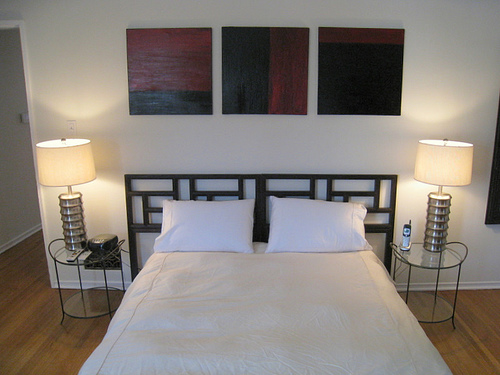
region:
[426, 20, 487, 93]
part of a white wall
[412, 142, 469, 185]
part of white lamp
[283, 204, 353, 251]
part of the left pillow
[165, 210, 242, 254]
part of the right pillow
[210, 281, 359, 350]
part of a white sheet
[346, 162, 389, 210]
part of the wooden part of the bed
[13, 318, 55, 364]
part of the floor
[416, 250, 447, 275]
part of a glassy furniture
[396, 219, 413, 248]
part of a cellphone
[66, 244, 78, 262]
part of a remote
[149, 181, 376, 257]
two white pillows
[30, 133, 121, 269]
lamp sitting on table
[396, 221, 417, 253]
phone sitting on stand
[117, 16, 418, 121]
three pictures hanging on the wall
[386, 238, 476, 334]
stand on wooden floor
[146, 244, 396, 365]
cream bed throw covering bed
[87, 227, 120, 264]
alarm clock on night stand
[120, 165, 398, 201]
wooden headboard with square pattern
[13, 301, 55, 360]
brown wooden floor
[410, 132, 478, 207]
cream lamp shade on lamp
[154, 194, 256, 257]
White pillow on a bed.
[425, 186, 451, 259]
Silver table lamp.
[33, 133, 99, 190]
White lamp shade.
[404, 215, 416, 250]
Portable phone beside bed.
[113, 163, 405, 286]
Wooden rectangular head board.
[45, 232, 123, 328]
Circular glass end table.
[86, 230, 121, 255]
Silver bedside clock radio.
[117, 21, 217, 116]
Red and black art work.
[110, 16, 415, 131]
Three painted wall canvases.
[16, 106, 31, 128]
White light switch panel.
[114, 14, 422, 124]
three matching painting's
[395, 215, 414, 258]
a wireless phone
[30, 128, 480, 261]
two matching silver lamps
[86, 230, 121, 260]
a black alarm clock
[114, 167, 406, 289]
a wood headboard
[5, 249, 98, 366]
floor made of wood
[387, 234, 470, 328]
a metal and glass round table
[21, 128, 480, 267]
two lights that are on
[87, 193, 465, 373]
a nicely made bed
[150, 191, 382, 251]
two white fluffy pillows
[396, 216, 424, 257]
white cordless phone on table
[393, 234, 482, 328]
clear glass table at side of bed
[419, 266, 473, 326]
small legs on clear table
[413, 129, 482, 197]
round white lamp shade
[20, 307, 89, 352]
light brown wood floor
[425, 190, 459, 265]
shiny silver decorative lamp base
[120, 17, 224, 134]
large red and black picture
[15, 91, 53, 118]
edge of white wall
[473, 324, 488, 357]
white line on floor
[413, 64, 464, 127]
light reflecting on white wall